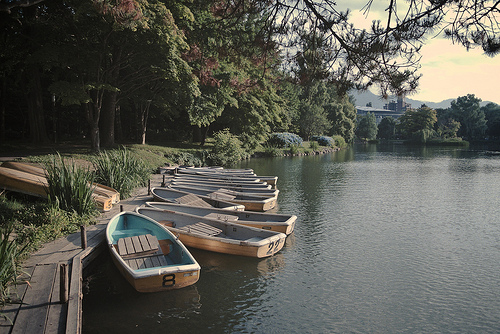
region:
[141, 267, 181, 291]
back part of a boat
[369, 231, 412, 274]
ripples of water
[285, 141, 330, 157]
edge of the lake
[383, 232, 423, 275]
part of the lakes water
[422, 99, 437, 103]
part of a hilly terrain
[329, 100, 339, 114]
leaves of a tree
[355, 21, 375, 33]
branches of a tree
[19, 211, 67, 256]
plantations on the edge of the lake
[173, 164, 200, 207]
group of boats on the dork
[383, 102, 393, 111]
a section of a house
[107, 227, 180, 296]
white boat at wooden dock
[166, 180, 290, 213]
white boat at wooden dock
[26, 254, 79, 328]
gray wooden boat dock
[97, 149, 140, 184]
green bushes next to boat dock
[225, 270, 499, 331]
calm green water in river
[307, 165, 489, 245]
calm green water in river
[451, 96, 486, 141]
green tree near river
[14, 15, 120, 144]
green tree near river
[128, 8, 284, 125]
green tree near river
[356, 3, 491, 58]
brown branches and green leaves on tree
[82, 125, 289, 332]
boats on a lake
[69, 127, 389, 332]
boats tied up to a pier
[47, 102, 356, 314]
row boats tied up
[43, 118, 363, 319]
a lot of row boats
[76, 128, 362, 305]
small boats in the water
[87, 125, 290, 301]
small row boats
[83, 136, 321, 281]
small row boats unaccompanied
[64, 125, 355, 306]
boats in calm water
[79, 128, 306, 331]
water in the water during the day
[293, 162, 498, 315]
calm waters during the day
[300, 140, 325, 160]
bushes at the edge of water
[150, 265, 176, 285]
a black letter on a boat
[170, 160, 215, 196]
boats tied to a dock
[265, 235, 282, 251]
black letters on a boat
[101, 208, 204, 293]
a boat tied to a dock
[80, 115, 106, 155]
a truck on a banck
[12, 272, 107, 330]
a catwalk along a lake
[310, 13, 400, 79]
a branch of a tree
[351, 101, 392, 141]
a rock bridge over water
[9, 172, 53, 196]
a wooden walkway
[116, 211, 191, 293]
small boat in lake with the number 8 on it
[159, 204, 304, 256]
small boat in river with the number 22 on it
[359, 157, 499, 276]
small lake with boats in it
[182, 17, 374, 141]
green trees near the lake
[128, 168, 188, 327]
shrubs near a lake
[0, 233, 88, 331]
pier next to lake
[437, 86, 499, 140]
trees near a lak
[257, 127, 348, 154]
shrubs near a lake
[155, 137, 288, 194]
boats near a lake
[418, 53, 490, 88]
sky over a lake